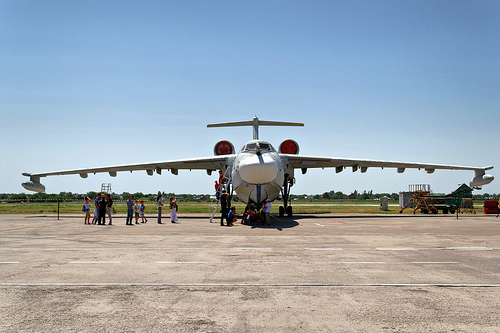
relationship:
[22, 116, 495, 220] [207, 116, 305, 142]
plane has a tail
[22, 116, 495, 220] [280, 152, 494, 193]
plane has a left wing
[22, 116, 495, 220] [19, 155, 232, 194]
plane has a right wing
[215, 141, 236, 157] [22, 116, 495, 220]
engine of plane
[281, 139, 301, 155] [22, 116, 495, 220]
engine of plane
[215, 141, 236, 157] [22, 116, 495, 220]
engine on plane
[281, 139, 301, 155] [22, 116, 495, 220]
engine on plane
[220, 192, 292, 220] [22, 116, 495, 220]
landing gear of plane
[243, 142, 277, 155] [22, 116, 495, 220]
windows on plane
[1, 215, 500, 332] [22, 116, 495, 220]
ground under plane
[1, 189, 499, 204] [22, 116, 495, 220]
trees behind plane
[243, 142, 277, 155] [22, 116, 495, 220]
windows on a plane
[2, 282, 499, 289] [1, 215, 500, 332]
line on ground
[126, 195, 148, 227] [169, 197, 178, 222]
people near person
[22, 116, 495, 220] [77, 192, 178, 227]
plane near people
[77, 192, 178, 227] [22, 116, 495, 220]
people near plane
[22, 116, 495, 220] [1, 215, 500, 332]
plane on ground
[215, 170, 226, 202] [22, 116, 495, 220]
people entering a plane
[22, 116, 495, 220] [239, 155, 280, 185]
plane has a nose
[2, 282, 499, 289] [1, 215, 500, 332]
line on a ground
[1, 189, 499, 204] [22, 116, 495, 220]
trees behind a plane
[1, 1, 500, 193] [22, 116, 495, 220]
sky above plane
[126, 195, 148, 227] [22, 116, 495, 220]
people near plane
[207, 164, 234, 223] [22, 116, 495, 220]
stairs on plane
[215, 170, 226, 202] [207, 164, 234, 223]
people on stairs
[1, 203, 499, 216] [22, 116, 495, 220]
grass behind plane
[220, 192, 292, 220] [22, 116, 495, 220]
landing gear under plane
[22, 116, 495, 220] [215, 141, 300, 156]
plane has red engines